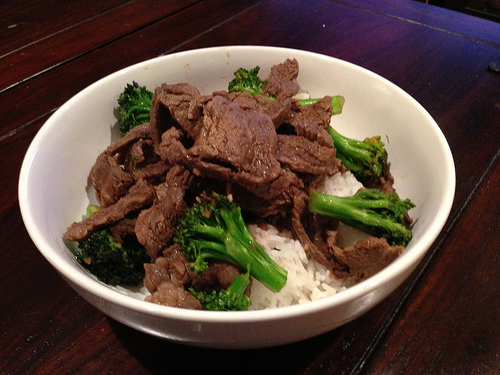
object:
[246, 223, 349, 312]
rice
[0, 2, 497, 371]
table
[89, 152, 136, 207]
beef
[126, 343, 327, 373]
shadow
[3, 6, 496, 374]
planks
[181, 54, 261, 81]
sauce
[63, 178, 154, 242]
beef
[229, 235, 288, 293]
stem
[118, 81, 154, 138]
broccoli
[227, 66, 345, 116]
broccoli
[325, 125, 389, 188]
broccoli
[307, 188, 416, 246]
broccoli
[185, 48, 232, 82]
juice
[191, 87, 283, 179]
man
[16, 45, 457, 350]
bowl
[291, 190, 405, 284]
beef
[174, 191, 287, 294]
broccoli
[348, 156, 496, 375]
crack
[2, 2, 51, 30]
crack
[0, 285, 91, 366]
crack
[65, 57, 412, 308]
steak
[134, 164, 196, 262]
beef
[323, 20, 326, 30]
spot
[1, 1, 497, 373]
brown table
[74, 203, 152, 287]
broccoli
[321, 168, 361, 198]
rice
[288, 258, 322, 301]
meal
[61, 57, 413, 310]
eatables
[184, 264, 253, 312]
broccoli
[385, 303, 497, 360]
board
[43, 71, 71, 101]
board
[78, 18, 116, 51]
board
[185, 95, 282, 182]
slice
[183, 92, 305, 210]
beef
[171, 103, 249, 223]
slice